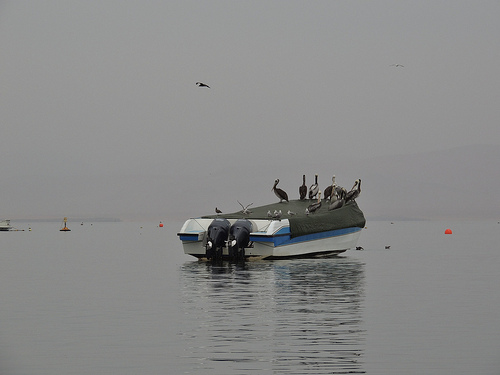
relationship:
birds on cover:
[281, 179, 398, 214] [231, 189, 378, 229]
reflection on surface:
[193, 252, 345, 374] [11, 281, 497, 364]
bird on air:
[194, 81, 210, 89] [10, 9, 490, 155]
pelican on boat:
[350, 182, 361, 206] [172, 187, 391, 265]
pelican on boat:
[325, 172, 343, 196] [172, 187, 391, 265]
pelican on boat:
[308, 172, 326, 197] [172, 187, 391, 265]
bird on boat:
[298, 175, 307, 200] [172, 187, 391, 265]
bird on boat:
[271, 178, 290, 203] [172, 187, 391, 265]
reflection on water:
[180, 251, 362, 374] [0, 1, 497, 373]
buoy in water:
[51, 214, 70, 236] [3, 196, 493, 372]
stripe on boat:
[265, 220, 356, 240] [101, 96, 401, 278]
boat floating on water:
[176, 199, 365, 261] [293, 257, 355, 268]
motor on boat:
[207, 219, 250, 263] [155, 121, 410, 288]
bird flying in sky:
[187, 76, 210, 96] [7, 13, 499, 160]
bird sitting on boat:
[271, 175, 288, 209] [167, 178, 373, 269]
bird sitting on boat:
[298, 172, 309, 200] [167, 178, 373, 269]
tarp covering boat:
[202, 196, 366, 241] [174, 196, 366, 269]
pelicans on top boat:
[263, 165, 371, 207] [176, 199, 365, 261]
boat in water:
[176, 199, 365, 261] [9, 226, 497, 364]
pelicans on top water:
[263, 165, 371, 207] [9, 226, 497, 364]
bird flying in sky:
[194, 81, 210, 89] [8, 5, 377, 70]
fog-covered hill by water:
[124, 160, 484, 225] [2, 222, 498, 373]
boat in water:
[186, 153, 359, 278] [9, 226, 497, 364]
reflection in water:
[180, 251, 362, 374] [9, 226, 497, 364]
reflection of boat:
[180, 251, 362, 374] [186, 153, 359, 278]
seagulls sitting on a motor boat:
[206, 191, 263, 226] [181, 169, 403, 263]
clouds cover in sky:
[4, 3, 499, 228] [3, 2, 498, 214]